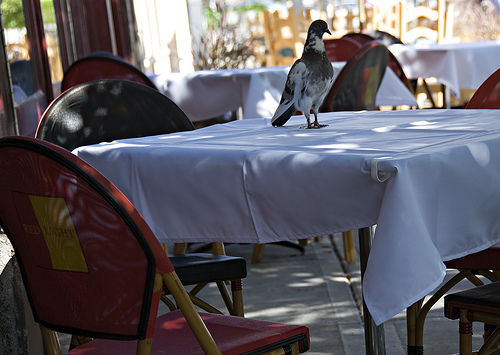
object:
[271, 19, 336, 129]
bird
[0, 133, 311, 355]
chair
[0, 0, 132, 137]
building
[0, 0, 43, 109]
window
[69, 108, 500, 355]
table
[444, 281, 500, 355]
chair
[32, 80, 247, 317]
chair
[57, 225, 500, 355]
ground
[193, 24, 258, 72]
bush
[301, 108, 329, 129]
feet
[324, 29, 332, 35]
beak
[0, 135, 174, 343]
back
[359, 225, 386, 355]
leg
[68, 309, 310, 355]
seat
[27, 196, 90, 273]
design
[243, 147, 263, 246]
fold line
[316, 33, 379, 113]
chair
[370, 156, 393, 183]
bracket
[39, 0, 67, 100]
door